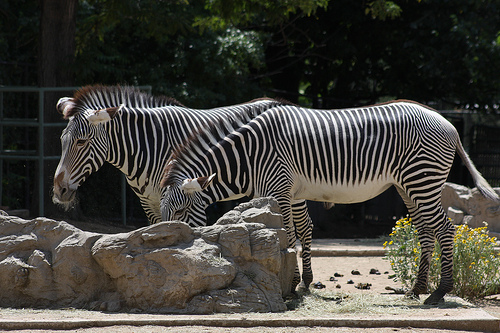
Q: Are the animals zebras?
A: Yes, all the animals are zebras.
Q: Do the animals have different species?
A: No, all the animals are zebras.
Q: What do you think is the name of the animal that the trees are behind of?
A: The animal is a zebra.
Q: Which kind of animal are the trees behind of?
A: The trees are behind the zebra.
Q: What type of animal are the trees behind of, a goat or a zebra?
A: The trees are behind a zebra.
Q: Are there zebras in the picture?
A: Yes, there is a zebra.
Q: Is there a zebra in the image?
A: Yes, there is a zebra.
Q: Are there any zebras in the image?
A: Yes, there is a zebra.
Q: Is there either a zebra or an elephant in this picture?
A: Yes, there is a zebra.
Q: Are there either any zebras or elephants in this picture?
A: Yes, there is a zebra.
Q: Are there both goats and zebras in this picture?
A: No, there is a zebra but no goats.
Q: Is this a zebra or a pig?
A: This is a zebra.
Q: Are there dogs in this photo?
A: No, there are no dogs.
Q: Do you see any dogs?
A: No, there are no dogs.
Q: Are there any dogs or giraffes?
A: No, there are no dogs or giraffes.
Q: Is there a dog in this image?
A: No, there are no dogs.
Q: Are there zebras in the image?
A: Yes, there is a zebra.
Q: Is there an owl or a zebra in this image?
A: Yes, there is a zebra.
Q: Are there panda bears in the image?
A: No, there are no panda bears.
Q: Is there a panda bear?
A: No, there are no panda bears.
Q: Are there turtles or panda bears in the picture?
A: No, there are no panda bears or turtles.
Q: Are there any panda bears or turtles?
A: No, there are no panda bears or turtles.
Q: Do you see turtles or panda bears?
A: No, there are no panda bears or turtles.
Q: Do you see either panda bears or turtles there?
A: No, there are no panda bears or turtles.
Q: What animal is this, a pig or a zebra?
A: This is a zebra.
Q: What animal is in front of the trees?
A: The zebra is in front of the trees.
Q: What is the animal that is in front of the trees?
A: The animal is a zebra.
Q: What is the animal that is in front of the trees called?
A: The animal is a zebra.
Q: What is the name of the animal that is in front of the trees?
A: The animal is a zebra.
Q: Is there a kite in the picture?
A: No, there are no kites.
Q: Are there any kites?
A: No, there are no kites.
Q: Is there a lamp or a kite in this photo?
A: No, there are no kites or lamps.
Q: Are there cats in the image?
A: No, there are no cats.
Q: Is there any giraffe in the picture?
A: No, there are no giraffes.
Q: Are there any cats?
A: No, there are no cats.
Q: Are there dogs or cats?
A: No, there are no cats or dogs.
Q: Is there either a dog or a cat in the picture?
A: No, there are no cats or dogs.